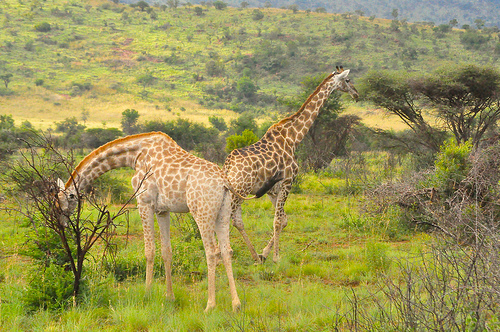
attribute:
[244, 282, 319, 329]
grass — tall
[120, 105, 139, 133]
tree — bright green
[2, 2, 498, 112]
hill — grassy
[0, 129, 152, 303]
bush — bare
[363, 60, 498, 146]
tree — green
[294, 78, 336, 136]
neck — long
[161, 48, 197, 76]
tree — bright green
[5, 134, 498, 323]
grass — green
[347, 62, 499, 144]
tree — large bush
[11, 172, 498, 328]
field — middle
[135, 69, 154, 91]
tree — bright green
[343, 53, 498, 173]
tree — tall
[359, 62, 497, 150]
large bush — dark green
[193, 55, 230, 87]
tree — bright green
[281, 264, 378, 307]
grass — green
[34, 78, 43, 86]
tree — bright green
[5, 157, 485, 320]
area — green, grassy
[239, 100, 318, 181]
spots — brown